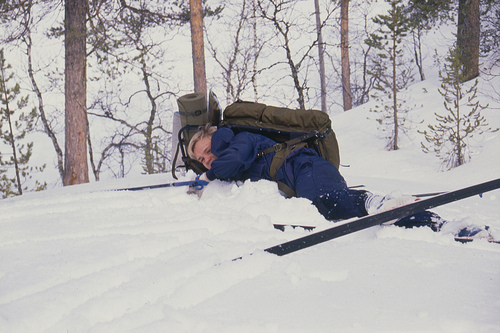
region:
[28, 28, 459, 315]
a skiier who fell down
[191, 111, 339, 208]
a man in a blue jacket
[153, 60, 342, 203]
a man wearing a backpacking pack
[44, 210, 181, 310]
fluffy white snow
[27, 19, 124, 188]
the trunk of a pine tree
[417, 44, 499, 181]
a young pine tree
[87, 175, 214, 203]
a ski pole in the snow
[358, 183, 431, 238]
a white ski boot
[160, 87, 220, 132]
a green bed roll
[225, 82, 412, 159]
an army green backpack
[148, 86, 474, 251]
skier laying in snow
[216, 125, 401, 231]
blue suit of skier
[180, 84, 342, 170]
olive colored backpack of skier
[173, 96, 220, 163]
bedroll on olive colored backpack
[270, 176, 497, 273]
dark colored ski of skier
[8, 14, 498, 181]
tree trunks along mountainside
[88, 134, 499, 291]
snow skier is laying in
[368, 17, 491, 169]
tree saplings growing in snow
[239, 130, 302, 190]
straps of the backpack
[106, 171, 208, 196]
ski pole of skier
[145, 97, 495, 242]
Boy in the snow.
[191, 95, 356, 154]
Boy is carrying an outdoor backpack.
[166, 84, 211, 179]
Brown roll above the backpack.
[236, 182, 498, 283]
The boy is wearing skis.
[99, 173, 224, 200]
Ski pole on the wrist.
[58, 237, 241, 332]
Tracks in the snow.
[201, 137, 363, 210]
The snowsuit is blue.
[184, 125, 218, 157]
The boy has blonde hair.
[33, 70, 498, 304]
Boy is on top of a hill.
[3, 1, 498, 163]
Trees in the background.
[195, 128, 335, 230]
the jacket is blue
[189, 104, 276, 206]
the jacket is blue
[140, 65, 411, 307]
a man on the ground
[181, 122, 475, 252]
A boy laying on snow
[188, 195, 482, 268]
Ski's attached to boys feet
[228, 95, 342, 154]
A green backpack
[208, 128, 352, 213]
A blue ski suit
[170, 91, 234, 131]
A brown bedroll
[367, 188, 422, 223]
White colored ski boots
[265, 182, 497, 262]
A metal ski attached to boys boot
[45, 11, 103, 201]
A pine tree trunk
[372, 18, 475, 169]
Two very small trees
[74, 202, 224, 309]
Marks in the snow